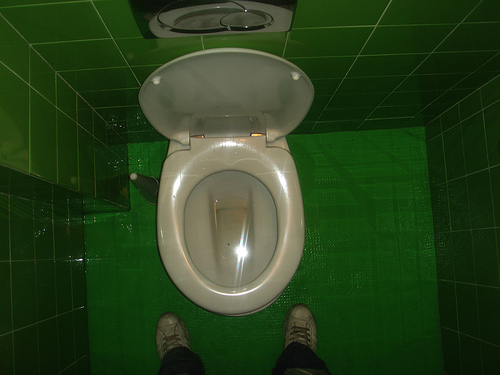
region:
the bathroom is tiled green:
[11, 19, 491, 366]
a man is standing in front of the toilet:
[145, 303, 332, 370]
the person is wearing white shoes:
[153, 305, 321, 362]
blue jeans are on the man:
[150, 342, 331, 374]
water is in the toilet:
[207, 191, 259, 268]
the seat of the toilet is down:
[153, 140, 305, 312]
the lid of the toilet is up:
[138, 47, 313, 148]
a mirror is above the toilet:
[122, 0, 303, 45]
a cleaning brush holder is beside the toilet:
[123, 163, 162, 214]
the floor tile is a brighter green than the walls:
[91, 137, 454, 367]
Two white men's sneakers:
[153, 305, 322, 352]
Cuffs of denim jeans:
[155, 342, 330, 374]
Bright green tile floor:
[81, 124, 448, 374]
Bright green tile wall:
[424, 71, 498, 373]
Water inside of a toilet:
[182, 169, 279, 289]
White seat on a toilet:
[152, 136, 305, 319]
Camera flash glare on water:
[233, 219, 253, 282]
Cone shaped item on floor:
[122, 171, 159, 201]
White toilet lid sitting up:
[135, 49, 316, 153]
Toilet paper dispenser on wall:
[125, 1, 298, 43]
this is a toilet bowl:
[111, 38, 346, 311]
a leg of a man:
[276, 295, 333, 372]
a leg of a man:
[138, 302, 205, 372]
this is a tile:
[19, 43, 66, 95]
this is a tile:
[291, 21, 363, 58]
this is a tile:
[446, 101, 495, 176]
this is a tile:
[31, 200, 53, 253]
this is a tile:
[13, 255, 40, 323]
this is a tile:
[26, 253, 63, 321]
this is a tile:
[46, 195, 83, 263]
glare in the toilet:
[229, 240, 256, 262]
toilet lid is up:
[128, 50, 321, 162]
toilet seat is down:
[147, 135, 314, 322]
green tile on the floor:
[63, 128, 438, 373]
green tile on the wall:
[423, 81, 499, 371]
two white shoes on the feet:
[142, 303, 328, 360]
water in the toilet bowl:
[208, 193, 252, 255]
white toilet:
[126, 48, 331, 328]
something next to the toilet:
[122, 165, 160, 206]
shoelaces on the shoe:
[288, 320, 310, 342]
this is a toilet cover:
[130, 53, 315, 143]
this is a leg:
[276, 295, 341, 367]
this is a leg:
[144, 308, 198, 363]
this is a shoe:
[280, 304, 326, 353]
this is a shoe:
[140, 305, 202, 356]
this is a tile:
[54, 107, 82, 187]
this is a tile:
[25, 206, 58, 265]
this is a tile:
[29, 90, 56, 177]